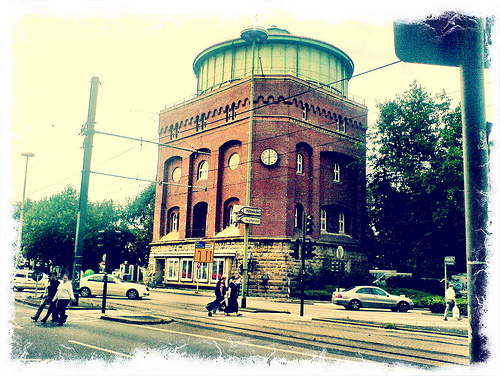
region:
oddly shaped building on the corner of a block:
[136, 18, 377, 294]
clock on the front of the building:
[258, 143, 282, 173]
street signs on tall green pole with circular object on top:
[238, 10, 268, 312]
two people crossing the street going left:
[28, 266, 84, 331]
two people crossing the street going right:
[203, 269, 254, 322]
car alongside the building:
[328, 220, 413, 314]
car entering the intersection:
[71, 260, 153, 306]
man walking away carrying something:
[441, 276, 466, 327]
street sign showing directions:
[193, 232, 214, 295]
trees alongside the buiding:
[342, 75, 487, 286]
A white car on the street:
[78, 273, 150, 298]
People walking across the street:
[31, 272, 73, 324]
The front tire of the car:
[125, 286, 140, 298]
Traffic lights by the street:
[288, 210, 315, 315]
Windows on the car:
[351, 288, 383, 295]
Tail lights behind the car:
[332, 290, 342, 299]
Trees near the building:
[20, 192, 146, 279]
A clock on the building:
[261, 148, 278, 165]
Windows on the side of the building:
[318, 210, 345, 231]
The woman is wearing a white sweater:
[51, 280, 74, 301]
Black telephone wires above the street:
[277, 78, 455, 175]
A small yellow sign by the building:
[188, 245, 220, 267]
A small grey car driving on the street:
[328, 271, 420, 319]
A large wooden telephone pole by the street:
[71, 68, 99, 301]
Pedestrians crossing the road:
[205, 270, 247, 318]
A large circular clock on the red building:
[256, 143, 290, 171]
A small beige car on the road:
[79, 274, 151, 306]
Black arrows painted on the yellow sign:
[194, 248, 216, 264]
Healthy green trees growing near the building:
[34, 188, 164, 271]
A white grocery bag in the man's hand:
[451, 303, 468, 325]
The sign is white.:
[233, 202, 265, 228]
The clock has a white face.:
[255, 142, 282, 166]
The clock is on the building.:
[247, 135, 282, 165]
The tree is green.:
[362, 88, 456, 294]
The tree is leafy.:
[368, 87, 464, 292]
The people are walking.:
[204, 268, 244, 353]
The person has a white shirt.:
[46, 281, 81, 301]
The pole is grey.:
[73, 77, 89, 284]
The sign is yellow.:
[188, 248, 215, 265]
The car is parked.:
[329, 277, 422, 319]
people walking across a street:
[113, 269, 355, 331]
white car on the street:
[73, 261, 190, 308]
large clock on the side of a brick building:
[253, 140, 283, 185]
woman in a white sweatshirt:
[51, 271, 79, 326]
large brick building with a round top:
[138, 19, 378, 301]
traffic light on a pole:
[296, 201, 322, 321]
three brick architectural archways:
[156, 136, 248, 256]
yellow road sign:
[191, 245, 221, 267]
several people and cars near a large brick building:
[5, 8, 485, 362]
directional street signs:
[235, 201, 266, 284]